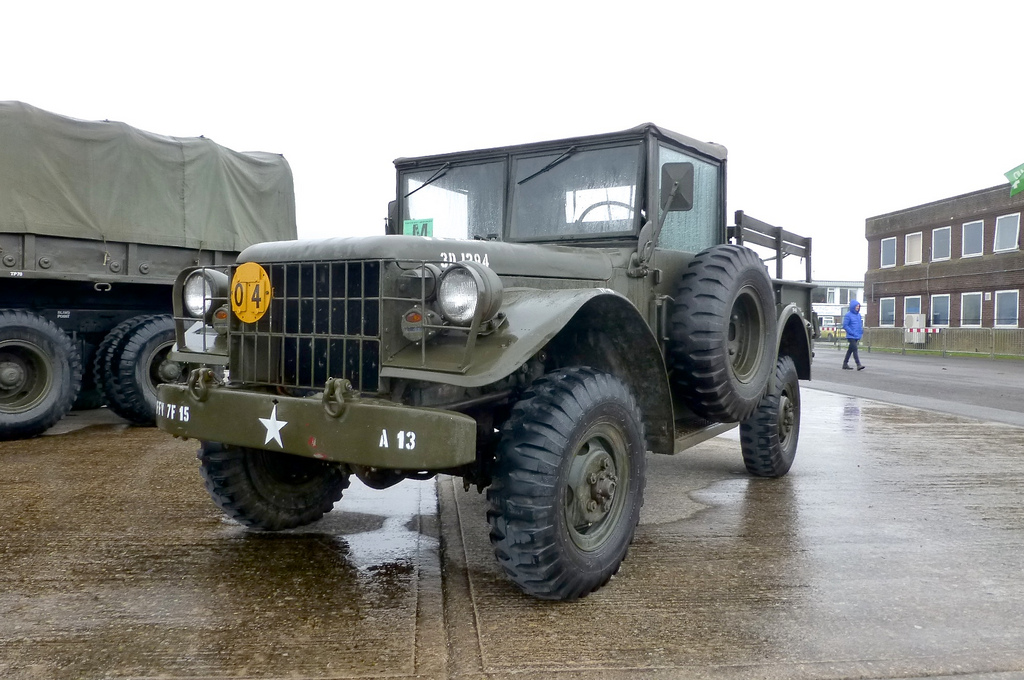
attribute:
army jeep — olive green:
[175, 115, 845, 621]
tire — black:
[661, 242, 768, 405]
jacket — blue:
[828, 314, 868, 341]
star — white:
[244, 392, 297, 453]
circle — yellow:
[214, 255, 277, 344]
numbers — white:
[394, 420, 427, 455]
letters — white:
[355, 409, 392, 453]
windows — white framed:
[873, 219, 1001, 263]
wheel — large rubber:
[169, 422, 353, 556]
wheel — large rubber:
[445, 342, 666, 610]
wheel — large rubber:
[662, 221, 783, 427]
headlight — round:
[163, 258, 243, 332]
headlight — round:
[420, 247, 500, 332]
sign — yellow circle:
[210, 243, 280, 343]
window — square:
[925, 225, 973, 280]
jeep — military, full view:
[121, 109, 834, 656]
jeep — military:
[119, 104, 824, 612]